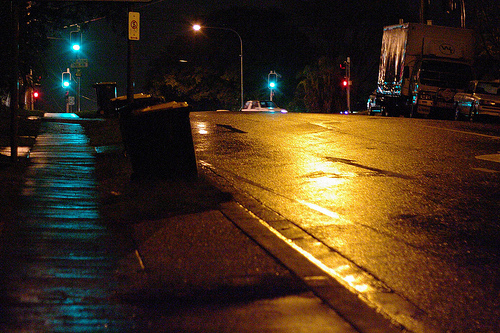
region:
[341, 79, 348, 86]
Red do not walk light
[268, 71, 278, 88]
Traffic light with green lit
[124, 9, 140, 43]
White street sign on a post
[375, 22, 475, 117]
Truck parked on the street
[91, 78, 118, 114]
Garbage can on the side of street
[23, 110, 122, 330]
Sidewalk next to street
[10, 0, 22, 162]
Wooden utility pole in a yard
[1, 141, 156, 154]
Driveway leading to the street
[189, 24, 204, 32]
Street light lighting the road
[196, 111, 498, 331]
Light reflecting on a wet street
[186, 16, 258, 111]
A street light that is on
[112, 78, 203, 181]
Trash can bins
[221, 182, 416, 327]
A curb on a side walk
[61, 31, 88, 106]
Two green stop lights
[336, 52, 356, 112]
A red stop light for pedestrains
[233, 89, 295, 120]
A white car driving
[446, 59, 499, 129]
a parked car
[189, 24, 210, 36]
a light that is on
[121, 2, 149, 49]
A no parking sign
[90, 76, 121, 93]
the lid of a trash can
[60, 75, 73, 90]
green signal light on post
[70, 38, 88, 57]
green signal light on post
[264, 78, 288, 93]
green signal light on post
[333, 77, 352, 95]
red signal light on post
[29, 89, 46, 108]
red signal light on post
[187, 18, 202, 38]
red signal light on post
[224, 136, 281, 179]
wet black pavement on street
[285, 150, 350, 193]
wet black pavement on street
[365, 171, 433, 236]
wet black pavement on street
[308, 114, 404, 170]
wet black pavement on street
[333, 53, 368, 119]
The light pole is grey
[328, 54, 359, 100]
The light is red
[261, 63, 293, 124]
The light signal is green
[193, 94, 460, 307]
The street is wet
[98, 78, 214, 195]
Trash cans on the curb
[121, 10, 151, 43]
White and red sign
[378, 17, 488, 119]
Cars parked on the street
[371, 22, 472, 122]
The truck is white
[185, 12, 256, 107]
Tall grey light pole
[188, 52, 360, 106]
Trees behind the light signal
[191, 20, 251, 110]
brightly lit street light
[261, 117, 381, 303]
light reflecting on the street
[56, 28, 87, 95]
pair of bright blue lights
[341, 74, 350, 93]
bright red light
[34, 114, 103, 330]
blue light reflecting on the sidewalk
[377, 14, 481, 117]
big white truck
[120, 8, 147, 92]
white street sign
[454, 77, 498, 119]
car parked on the street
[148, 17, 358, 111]
big bushy green trees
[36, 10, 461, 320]
a street at night